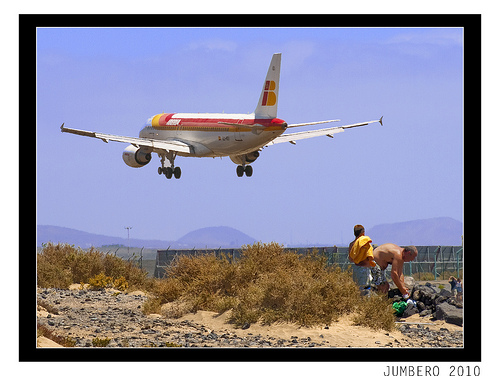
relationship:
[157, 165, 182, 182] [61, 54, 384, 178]
landing gear on airplane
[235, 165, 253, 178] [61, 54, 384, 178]
landing gear on airplane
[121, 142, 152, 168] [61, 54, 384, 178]
engine on airplane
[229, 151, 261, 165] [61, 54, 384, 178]
engine on airplane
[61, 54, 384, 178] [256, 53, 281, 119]
airplane has tail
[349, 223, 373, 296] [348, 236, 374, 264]
man holding shirt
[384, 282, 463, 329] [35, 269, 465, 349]
rocks on beach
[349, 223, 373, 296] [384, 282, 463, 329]
man near rocks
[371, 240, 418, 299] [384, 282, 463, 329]
man near rocks